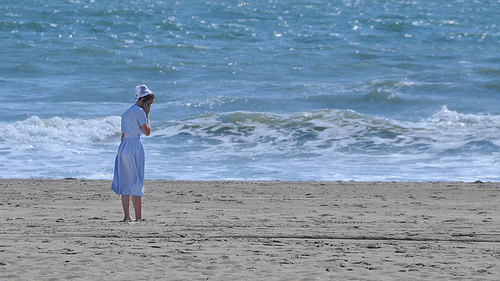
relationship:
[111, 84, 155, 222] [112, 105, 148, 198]
woman wearing dress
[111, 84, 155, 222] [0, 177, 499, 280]
woman standing on beach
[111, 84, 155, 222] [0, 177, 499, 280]
woman on beach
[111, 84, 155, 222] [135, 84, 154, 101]
woman wearing hat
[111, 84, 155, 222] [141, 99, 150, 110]
woman talks on phone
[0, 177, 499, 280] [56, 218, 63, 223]
beach has sand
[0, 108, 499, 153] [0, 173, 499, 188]
wave near shore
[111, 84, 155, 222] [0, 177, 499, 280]
woman standing at beach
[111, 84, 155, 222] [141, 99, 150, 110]
woman holding phone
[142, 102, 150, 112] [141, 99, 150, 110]
hand holds phone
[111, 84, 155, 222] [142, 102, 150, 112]
woman has hand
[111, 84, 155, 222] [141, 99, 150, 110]
woman talking on phone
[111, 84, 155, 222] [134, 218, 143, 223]
woman has foot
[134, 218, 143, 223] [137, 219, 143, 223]
foot touches sand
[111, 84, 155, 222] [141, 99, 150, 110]
woman holds phone